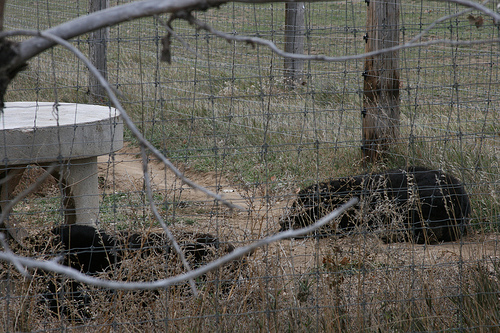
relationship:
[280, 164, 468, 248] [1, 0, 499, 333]
dog enclosed behind fence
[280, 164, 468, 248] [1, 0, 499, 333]
dog behind fence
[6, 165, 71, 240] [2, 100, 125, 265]
space beneath structure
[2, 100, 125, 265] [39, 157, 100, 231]
structure has leg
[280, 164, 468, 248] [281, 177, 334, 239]
dog has head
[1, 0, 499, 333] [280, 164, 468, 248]
fence holding dog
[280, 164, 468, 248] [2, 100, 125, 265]
dog laying near structure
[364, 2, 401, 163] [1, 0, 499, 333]
post holds fence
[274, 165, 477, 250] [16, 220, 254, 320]
bear near bear